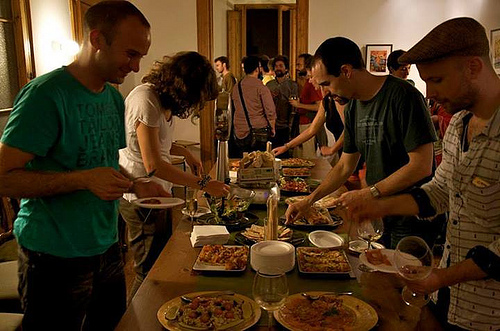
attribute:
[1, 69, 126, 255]
t-shirt — green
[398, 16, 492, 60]
hat — brown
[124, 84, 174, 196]
shirt — white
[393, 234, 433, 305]
wine glass — goblet, empty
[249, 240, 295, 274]
plates — paper plates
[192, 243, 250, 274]
serving dishes — square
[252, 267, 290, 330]
goblet — empty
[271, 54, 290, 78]
mustache — black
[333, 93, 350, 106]
beard — black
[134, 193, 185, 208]
plate — paper plate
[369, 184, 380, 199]
wrist watch — silver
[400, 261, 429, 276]
wine — white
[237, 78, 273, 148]
shoulder bag — black